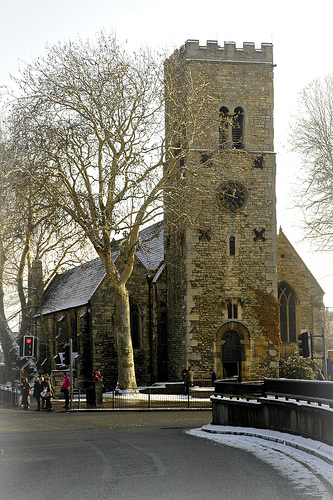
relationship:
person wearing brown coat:
[183, 365, 194, 385] [185, 370, 193, 379]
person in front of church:
[29, 375, 46, 413] [27, 39, 331, 382]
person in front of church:
[18, 377, 31, 410] [27, 39, 331, 382]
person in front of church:
[43, 373, 54, 411] [27, 39, 331, 382]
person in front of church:
[90, 365, 108, 387] [27, 39, 331, 382]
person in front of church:
[61, 372, 71, 408] [27, 39, 331, 382]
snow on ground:
[192, 387, 330, 488] [138, 423, 248, 498]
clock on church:
[216, 178, 248, 212] [151, 44, 310, 412]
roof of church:
[36, 232, 142, 324] [163, 27, 293, 390]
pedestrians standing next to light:
[15, 363, 101, 411] [22, 335, 34, 357]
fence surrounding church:
[2, 387, 215, 406] [27, 39, 331, 382]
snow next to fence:
[192, 387, 330, 488] [214, 381, 330, 443]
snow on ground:
[192, 387, 330, 488] [3, 436, 332, 499]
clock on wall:
[218, 179, 248, 211] [182, 40, 278, 371]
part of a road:
[145, 454, 174, 478] [9, 421, 191, 498]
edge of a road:
[45, 415, 210, 454] [26, 411, 228, 499]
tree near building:
[5, 24, 194, 413] [10, 55, 332, 393]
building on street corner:
[121, 155, 290, 377] [33, 375, 253, 467]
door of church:
[201, 307, 271, 394] [67, 297, 125, 412]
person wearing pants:
[61, 372, 71, 408] [63, 389, 69, 413]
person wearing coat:
[208, 368, 217, 385] [210, 372, 216, 384]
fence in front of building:
[110, 382, 189, 407] [161, 39, 286, 304]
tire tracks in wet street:
[244, 424, 332, 500] [11, 357, 330, 499]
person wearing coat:
[55, 373, 76, 409] [59, 374, 69, 388]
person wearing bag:
[29, 378, 51, 411] [38, 380, 51, 399]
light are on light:
[22, 335, 34, 357] [22, 335, 34, 357]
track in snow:
[80, 403, 239, 490] [235, 427, 327, 475]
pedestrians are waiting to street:
[15, 363, 101, 411] [1, 395, 330, 496]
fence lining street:
[77, 382, 212, 408] [0, 407, 330, 498]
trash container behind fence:
[83, 376, 105, 408] [76, 381, 206, 407]